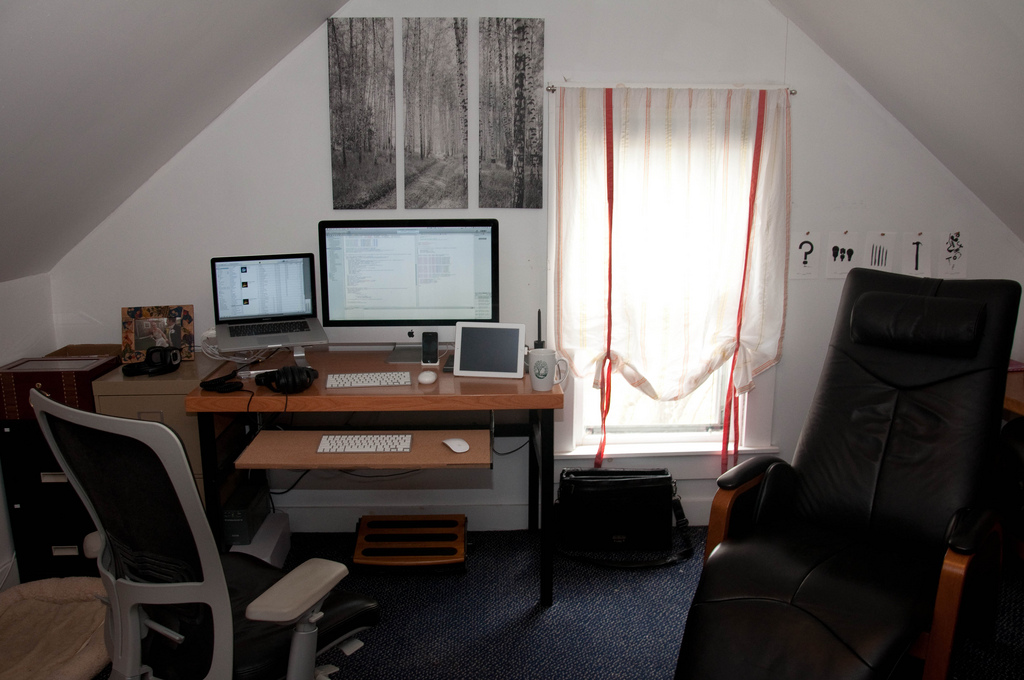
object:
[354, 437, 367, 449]
key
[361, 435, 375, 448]
key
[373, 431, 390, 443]
key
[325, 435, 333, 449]
key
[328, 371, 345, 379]
key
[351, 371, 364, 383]
key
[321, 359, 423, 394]
keyboard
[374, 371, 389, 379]
key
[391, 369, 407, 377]
key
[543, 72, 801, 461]
curtain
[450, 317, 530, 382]
tablet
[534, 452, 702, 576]
laptop bag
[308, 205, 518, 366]
computer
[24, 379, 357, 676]
office chair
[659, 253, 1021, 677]
chair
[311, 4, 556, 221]
sepia triptych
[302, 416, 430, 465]
computer keyboard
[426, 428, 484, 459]
computer mouse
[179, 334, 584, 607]
computer desk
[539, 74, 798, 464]
window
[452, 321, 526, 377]
screen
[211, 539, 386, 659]
cushion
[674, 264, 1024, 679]
cushions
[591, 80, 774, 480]
drawstring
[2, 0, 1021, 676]
room